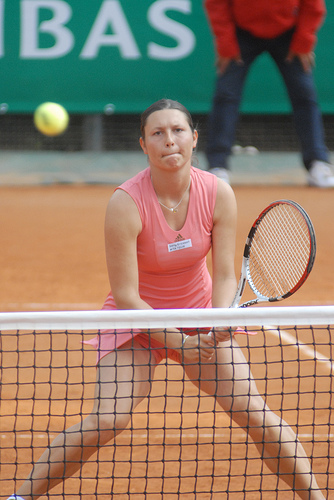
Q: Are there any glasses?
A: No, there are no glasses.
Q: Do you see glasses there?
A: No, there are no glasses.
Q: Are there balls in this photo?
A: Yes, there is a ball.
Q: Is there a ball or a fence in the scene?
A: Yes, there is a ball.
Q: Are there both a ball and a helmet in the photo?
A: No, there is a ball but no helmets.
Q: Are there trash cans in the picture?
A: No, there are no trash cans.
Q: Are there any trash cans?
A: No, there are no trash cans.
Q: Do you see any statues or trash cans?
A: No, there are no trash cans or statues.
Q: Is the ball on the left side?
A: Yes, the ball is on the left of the image.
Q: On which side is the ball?
A: The ball is on the left of the image.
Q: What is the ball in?
A: The ball is in the air.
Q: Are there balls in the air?
A: Yes, there is a ball in the air.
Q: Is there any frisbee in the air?
A: No, there is a ball in the air.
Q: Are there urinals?
A: No, there are no urinals.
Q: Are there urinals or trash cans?
A: No, there are no urinals or trash cans.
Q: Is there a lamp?
A: No, there are no lamps.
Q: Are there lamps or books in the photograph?
A: No, there are no lamps or books.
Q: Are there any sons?
A: No, there are no sons.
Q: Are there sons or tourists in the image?
A: No, there are no sons or tourists.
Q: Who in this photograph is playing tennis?
A: The player is playing tennis.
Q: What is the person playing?
A: The player is playing tennis.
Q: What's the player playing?
A: The player is playing tennis.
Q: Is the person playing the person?
A: Yes, the player is playing tennis.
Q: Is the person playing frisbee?
A: No, the player is playing tennis.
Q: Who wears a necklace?
A: The player wears a necklace.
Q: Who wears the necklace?
A: The player wears a necklace.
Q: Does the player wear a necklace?
A: Yes, the player wears a necklace.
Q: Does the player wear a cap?
A: No, the player wears a necklace.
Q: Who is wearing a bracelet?
A: The player is wearing a bracelet.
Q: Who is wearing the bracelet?
A: The player is wearing a bracelet.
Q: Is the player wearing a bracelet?
A: Yes, the player is wearing a bracelet.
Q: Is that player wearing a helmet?
A: No, the player is wearing a bracelet.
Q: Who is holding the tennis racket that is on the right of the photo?
A: The player is holding the racket.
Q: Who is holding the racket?
A: The player is holding the racket.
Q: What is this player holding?
A: The player is holding the racket.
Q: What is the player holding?
A: The player is holding the racket.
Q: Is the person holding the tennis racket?
A: Yes, the player is holding the tennis racket.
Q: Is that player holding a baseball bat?
A: No, the player is holding the tennis racket.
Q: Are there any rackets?
A: Yes, there is a racket.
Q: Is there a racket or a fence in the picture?
A: Yes, there is a racket.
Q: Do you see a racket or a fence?
A: Yes, there is a racket.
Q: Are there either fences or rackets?
A: Yes, there is a racket.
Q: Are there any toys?
A: No, there are no toys.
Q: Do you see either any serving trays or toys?
A: No, there are no toys or serving trays.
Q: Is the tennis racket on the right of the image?
A: Yes, the tennis racket is on the right of the image.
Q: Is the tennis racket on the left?
A: No, the tennis racket is on the right of the image.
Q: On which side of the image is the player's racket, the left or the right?
A: The tennis racket is on the right of the image.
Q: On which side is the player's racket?
A: The racket is on the right of the image.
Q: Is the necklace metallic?
A: Yes, the necklace is metallic.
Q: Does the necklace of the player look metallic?
A: Yes, the necklace is metallic.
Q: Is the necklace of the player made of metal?
A: Yes, the necklace is made of metal.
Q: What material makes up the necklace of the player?
A: The necklace is made of metal.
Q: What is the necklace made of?
A: The necklace is made of metal.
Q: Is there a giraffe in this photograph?
A: No, there are no giraffes.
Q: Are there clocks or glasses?
A: No, there are no glasses or clocks.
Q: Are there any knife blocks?
A: No, there are no knife blocks.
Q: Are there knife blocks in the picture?
A: No, there are no knife blocks.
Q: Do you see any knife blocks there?
A: No, there are no knife blocks.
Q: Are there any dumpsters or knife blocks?
A: No, there are no knife blocks or dumpsters.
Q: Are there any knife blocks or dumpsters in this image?
A: No, there are no knife blocks or dumpsters.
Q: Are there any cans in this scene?
A: No, there are no cans.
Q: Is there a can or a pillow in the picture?
A: No, there are no cans or pillows.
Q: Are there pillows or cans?
A: No, there are no cans or pillows.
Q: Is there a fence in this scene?
A: Yes, there is a fence.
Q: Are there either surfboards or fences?
A: Yes, there is a fence.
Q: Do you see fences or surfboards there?
A: Yes, there is a fence.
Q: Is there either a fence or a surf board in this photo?
A: Yes, there is a fence.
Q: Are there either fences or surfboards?
A: Yes, there is a fence.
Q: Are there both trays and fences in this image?
A: No, there is a fence but no trays.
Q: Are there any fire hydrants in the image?
A: No, there are no fire hydrants.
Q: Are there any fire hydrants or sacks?
A: No, there are no fire hydrants or sacks.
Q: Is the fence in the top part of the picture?
A: Yes, the fence is in the top of the image.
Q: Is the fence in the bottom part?
A: No, the fence is in the top of the image.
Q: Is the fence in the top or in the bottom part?
A: The fence is in the top of the image.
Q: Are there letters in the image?
A: Yes, there are letters.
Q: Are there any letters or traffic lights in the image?
A: Yes, there are letters.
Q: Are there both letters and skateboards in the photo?
A: No, there are letters but no skateboards.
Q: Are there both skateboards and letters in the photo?
A: No, there are letters but no skateboards.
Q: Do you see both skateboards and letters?
A: No, there are letters but no skateboards.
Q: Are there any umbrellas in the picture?
A: No, there are no umbrellas.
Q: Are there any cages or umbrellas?
A: No, there are no umbrellas or cages.